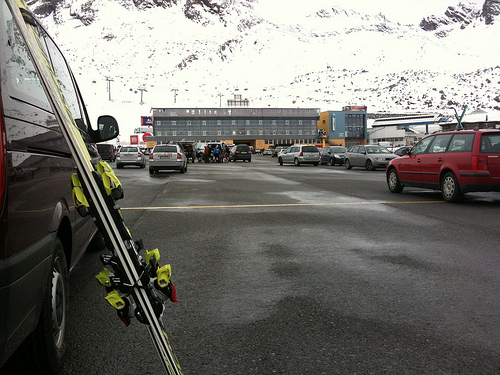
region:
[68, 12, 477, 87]
snow on the mountains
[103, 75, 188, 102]
poles in the snow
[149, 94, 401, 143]
a building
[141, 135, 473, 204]
cars parked in a parking lot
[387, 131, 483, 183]
a red car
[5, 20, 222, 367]
skis leaning against a car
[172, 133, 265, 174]
people standing in the parking lot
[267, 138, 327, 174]
a silver car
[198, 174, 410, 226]
water on the pavement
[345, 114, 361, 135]
windows on the building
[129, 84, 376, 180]
cars parked in parking lot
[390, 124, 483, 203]
the car is red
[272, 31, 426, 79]
snow on the mountain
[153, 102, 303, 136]
windows on the building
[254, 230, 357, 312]
water on the ground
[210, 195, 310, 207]
yellow line on street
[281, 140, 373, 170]
the cars are silver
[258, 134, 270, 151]
bottom of building is yellow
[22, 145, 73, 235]
the side of the car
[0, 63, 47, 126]
window of the car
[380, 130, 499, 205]
A car on the road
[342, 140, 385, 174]
A car on the road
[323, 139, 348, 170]
A car on the road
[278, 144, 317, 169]
A car on the road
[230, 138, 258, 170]
A car on the road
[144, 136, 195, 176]
A car on the road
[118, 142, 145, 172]
A car on the road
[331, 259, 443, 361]
A grey tarmac road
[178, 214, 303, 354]
A grey tarmac road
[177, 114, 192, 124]
window on the building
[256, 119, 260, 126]
window on the building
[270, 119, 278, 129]
window on the building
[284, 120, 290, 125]
window on the building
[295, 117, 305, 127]
window on the building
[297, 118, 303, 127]
window on the building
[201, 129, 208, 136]
window on the building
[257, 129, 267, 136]
window on the building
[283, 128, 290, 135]
window on the building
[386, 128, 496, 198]
red suv parked in street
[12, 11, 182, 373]
large snow board next to black van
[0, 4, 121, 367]
black van parked in street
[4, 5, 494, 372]
a bunch of cars in parking lot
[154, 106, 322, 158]
large gray building with dark roof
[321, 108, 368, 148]
small green and yellow building in the background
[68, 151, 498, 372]
large pavement parking lot with yellow lines on the ground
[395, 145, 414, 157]
small black rear view of red suv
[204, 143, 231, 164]
people standing in parking lot behind black suv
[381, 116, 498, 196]
red station wagon to right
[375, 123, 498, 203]
red station wagon to right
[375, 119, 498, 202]
red station wagon to right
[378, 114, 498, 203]
red station wagon to right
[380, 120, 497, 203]
red station wagon to right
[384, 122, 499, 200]
red station wagon to right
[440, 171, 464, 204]
Black tire of a car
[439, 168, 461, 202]
Tire of a red car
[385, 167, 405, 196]
Tire of a car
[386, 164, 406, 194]
Tire of a red car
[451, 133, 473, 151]
Window of a car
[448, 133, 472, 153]
Window of a red car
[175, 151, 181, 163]
Taillight of a car